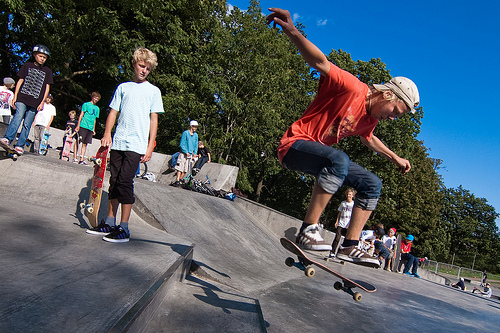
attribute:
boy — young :
[114, 51, 158, 240]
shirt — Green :
[74, 99, 99, 133]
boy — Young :
[106, 42, 185, 232]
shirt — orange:
[309, 61, 391, 149]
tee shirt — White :
[109, 80, 164, 155]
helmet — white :
[190, 114, 197, 127]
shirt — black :
[313, 106, 340, 123]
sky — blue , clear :
[371, 36, 482, 96]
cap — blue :
[405, 231, 420, 243]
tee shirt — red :
[275, 62, 379, 162]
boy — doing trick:
[266, 1, 419, 275]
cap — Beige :
[372, 73, 422, 114]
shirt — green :
[80, 101, 99, 131]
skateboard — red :
[59, 135, 72, 162]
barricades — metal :
[418, 250, 499, 290]